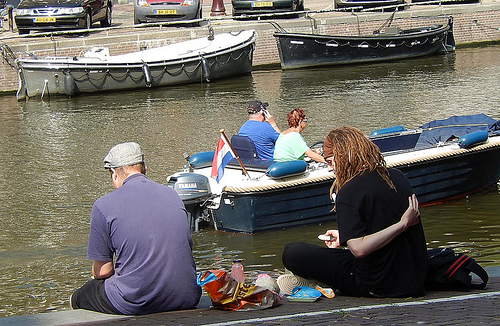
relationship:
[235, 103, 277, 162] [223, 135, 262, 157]
person leaning on backrest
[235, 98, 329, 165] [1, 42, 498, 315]
people boating on water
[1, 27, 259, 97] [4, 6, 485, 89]
boat parked along dock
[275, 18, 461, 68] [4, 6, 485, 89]
boat parked along dock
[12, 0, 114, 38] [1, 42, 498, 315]
car parked near water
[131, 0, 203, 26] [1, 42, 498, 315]
car parked near water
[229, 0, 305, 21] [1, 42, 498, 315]
car parked near water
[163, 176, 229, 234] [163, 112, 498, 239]
motor attached to boat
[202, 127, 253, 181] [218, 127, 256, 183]
flag hanging from flag pole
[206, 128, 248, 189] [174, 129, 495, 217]
pole attached to boat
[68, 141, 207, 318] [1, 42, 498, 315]
man sitting near water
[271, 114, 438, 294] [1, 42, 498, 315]
person sitting near water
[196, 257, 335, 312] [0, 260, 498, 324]
items on platform